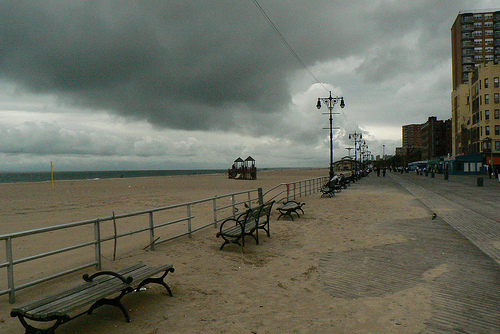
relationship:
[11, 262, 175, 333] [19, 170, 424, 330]
bench on sand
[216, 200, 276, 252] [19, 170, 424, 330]
bench on sand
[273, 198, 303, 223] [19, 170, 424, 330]
bench on sand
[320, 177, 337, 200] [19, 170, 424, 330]
bench on sand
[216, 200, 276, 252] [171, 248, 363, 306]
bench on sand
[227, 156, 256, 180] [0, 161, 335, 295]
hut on sand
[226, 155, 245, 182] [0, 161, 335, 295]
hut on sand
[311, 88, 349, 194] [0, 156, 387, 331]
street light on beach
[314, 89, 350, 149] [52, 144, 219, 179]
light on beach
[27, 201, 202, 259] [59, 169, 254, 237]
fence on beach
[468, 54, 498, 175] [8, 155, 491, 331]
building on beach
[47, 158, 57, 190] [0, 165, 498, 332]
pole in ground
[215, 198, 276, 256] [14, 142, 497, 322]
bench on beach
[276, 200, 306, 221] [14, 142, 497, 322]
bench on beach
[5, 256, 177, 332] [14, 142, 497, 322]
bench on beach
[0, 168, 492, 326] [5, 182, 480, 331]
beach covered in sand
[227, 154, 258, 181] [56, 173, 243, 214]
play set on bench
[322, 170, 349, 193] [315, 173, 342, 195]
people sitting on bench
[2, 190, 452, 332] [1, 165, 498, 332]
sand on boardwalk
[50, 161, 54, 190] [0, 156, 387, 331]
pole on beach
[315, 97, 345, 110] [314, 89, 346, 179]
light on light pole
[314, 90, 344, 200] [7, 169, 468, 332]
streetlight in sand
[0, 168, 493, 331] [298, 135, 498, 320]
beach against sidewalk